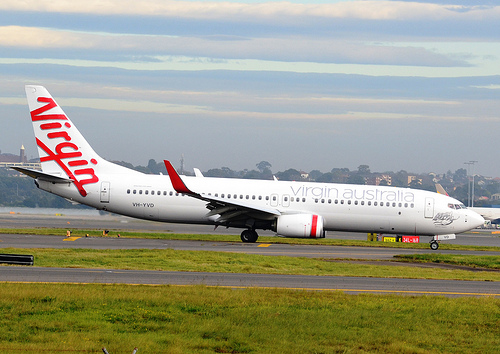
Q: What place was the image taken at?
A: It was taken at the airport.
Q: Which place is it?
A: It is an airport.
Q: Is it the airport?
A: Yes, it is the airport.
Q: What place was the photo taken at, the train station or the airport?
A: It was taken at the airport.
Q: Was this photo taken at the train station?
A: No, the picture was taken in the airport.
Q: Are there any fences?
A: No, there are no fences.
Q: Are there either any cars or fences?
A: No, there are no fences or cars.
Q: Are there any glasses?
A: No, there are no glasses.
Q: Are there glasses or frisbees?
A: No, there are no glasses or frisbees.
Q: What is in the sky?
A: The clouds are in the sky.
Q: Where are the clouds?
A: The clouds are in the sky.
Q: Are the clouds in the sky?
A: Yes, the clouds are in the sky.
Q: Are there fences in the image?
A: No, there are no fences.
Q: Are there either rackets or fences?
A: No, there are no fences or rackets.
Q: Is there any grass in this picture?
A: Yes, there is grass.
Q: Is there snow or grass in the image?
A: Yes, there is grass.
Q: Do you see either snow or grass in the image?
A: Yes, there is grass.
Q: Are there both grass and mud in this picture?
A: No, there is grass but no mud.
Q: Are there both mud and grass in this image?
A: No, there is grass but no mud.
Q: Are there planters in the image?
A: No, there are no planters.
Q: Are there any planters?
A: No, there are no planters.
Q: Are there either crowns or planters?
A: No, there are no planters or crowns.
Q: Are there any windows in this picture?
A: Yes, there are windows.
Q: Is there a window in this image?
A: Yes, there are windows.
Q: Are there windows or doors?
A: Yes, there are windows.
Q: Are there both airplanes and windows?
A: Yes, there are both windows and an airplane.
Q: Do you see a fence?
A: No, there are no fences.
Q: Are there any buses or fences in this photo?
A: No, there are no fences or buses.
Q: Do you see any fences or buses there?
A: No, there are no fences or buses.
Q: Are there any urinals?
A: No, there are no urinals.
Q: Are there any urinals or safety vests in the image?
A: No, there are no urinals or safety vests.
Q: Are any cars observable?
A: No, there are no cars.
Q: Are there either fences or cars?
A: No, there are no cars or fences.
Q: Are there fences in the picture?
A: No, there are no fences.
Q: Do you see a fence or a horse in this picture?
A: No, there are no fences or horses.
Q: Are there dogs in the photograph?
A: No, there are no dogs.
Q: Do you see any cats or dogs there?
A: No, there are no dogs or cats.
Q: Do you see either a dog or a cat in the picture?
A: No, there are no dogs or cats.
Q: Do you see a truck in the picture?
A: No, there are no trucks.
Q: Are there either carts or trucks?
A: No, there are no trucks or carts.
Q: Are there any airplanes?
A: Yes, there is an airplane.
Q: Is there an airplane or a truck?
A: Yes, there is an airplane.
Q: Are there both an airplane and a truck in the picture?
A: No, there is an airplane but no trucks.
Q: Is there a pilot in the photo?
A: No, there are no pilots.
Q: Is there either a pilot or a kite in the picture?
A: No, there are no pilots or kites.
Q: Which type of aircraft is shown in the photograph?
A: The aircraft is an airplane.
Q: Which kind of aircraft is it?
A: The aircraft is an airplane.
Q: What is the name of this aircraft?
A: This is an airplane.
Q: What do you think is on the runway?
A: The airplane is on the runway.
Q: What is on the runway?
A: The airplane is on the runway.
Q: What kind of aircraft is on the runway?
A: The aircraft is an airplane.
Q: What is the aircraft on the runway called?
A: The aircraft is an airplane.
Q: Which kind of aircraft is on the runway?
A: The aircraft is an airplane.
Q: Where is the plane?
A: The plane is on the runway.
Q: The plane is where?
A: The plane is on the runway.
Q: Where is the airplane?
A: The plane is on the runway.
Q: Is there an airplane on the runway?
A: Yes, there is an airplane on the runway.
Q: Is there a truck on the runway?
A: No, there is an airplane on the runway.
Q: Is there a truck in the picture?
A: No, there are no trucks.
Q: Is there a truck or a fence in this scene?
A: No, there are no trucks or fences.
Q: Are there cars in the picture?
A: No, there are no cars.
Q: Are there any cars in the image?
A: No, there are no cars.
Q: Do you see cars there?
A: No, there are no cars.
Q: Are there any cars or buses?
A: No, there are no cars or buses.